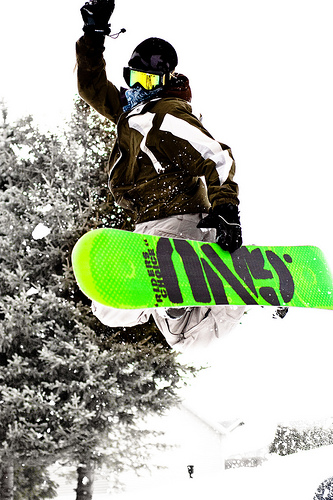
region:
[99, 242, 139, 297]
the board is yellow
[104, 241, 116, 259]
the board is yellow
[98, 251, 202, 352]
the board is yellow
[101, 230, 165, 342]
the board is yellow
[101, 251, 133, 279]
the board is yellow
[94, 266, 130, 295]
the board is yellow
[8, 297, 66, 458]
this is a tree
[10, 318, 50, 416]
the tree has many leaves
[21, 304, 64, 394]
the leaves are covered with snow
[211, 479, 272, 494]
this is the snow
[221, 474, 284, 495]
the snow is on the ground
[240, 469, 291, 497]
the snow is white in color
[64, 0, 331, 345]
this is a man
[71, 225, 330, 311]
this is a snowboard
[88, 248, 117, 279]
the snowboard is green in color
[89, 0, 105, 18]
the gloves are black in color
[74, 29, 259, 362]
the man is snow skating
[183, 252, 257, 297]
this is a skate board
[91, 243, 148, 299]
the skate board is green in color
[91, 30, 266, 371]
the man is on air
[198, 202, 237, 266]
the hand is on the board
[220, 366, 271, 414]
the place is full of snow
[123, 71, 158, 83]
he is wearing goggles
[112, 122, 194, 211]
the jacket is warm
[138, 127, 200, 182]
the jacket is brown in color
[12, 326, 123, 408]
the trees is filled with snow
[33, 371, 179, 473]
the trees is filled with snow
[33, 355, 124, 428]
the trees is filled with snow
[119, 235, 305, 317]
green and black snowboard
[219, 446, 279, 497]
snow on the ground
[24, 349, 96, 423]
tree next to the man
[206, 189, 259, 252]
black glove of the man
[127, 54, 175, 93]
goggles on the man's face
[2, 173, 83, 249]
snow on the trees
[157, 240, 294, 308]
letters on the snowboard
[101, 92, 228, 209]
brown and white sweater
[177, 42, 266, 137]
white background of photo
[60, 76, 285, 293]
snowboarder in the air